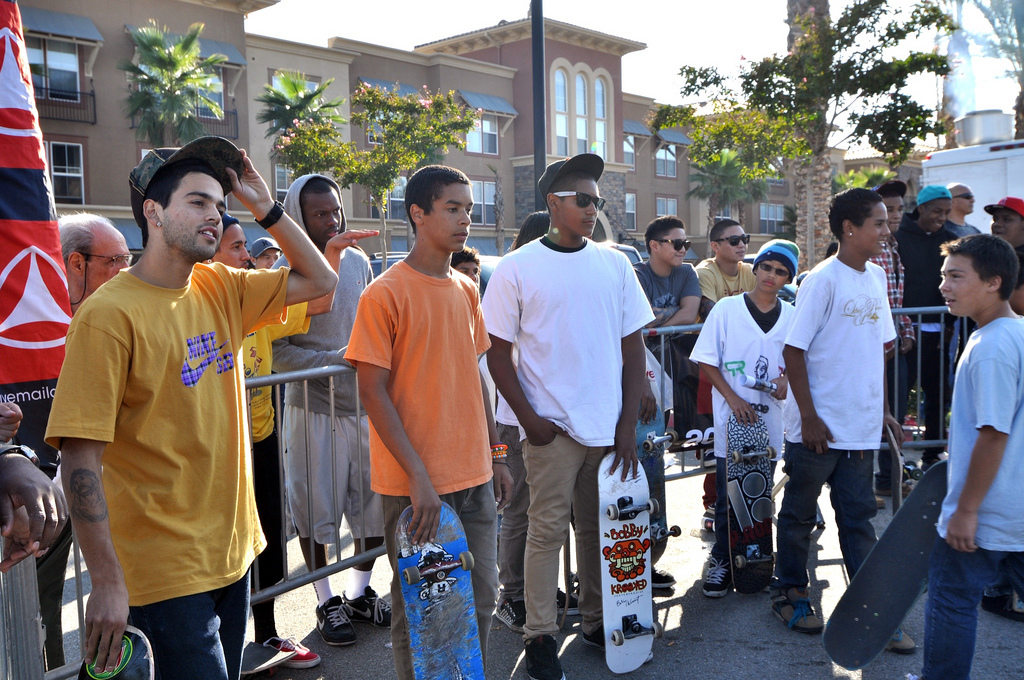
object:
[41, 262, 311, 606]
shirt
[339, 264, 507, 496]
shirt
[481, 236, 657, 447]
shirt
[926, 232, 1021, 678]
boy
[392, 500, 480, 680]
skateboar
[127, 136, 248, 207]
hat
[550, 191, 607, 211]
sunglasses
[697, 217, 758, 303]
men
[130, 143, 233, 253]
head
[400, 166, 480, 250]
head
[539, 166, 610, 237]
head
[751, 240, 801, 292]
head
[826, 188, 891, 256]
head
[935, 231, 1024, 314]
head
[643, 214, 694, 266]
head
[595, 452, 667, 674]
board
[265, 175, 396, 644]
people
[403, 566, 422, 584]
wheels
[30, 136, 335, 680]
man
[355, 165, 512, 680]
boy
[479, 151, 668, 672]
boy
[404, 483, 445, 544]
hand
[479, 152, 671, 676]
man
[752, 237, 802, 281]
hat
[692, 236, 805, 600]
man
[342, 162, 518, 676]
man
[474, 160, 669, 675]
man